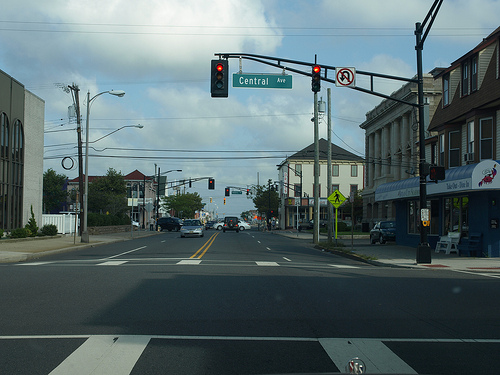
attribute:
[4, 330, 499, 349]
line — white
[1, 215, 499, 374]
road — grey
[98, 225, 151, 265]
line — white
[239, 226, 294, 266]
line — white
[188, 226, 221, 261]
line — yellow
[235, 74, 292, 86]
sign — green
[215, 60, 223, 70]
light — red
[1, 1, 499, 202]
sky — blue, cloudy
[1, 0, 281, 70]
cloud — white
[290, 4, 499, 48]
cloud — white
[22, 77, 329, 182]
cloud — white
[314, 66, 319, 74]
light — red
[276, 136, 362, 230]
house — white, brick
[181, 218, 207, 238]
car — silver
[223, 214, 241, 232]
jeep — red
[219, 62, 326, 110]
stop lights — red 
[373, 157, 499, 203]
awning — long, white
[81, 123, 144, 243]
lamp post — white 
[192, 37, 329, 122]
sign — green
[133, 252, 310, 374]
lines — white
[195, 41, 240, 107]
traffic light — red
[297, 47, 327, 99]
traffic light — red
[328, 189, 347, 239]
sign — bright yellow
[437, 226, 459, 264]
chair — white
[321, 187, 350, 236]
sign — yellow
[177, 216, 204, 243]
car — silver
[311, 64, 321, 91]
light — red, suspended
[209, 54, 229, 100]
light — red, suspended